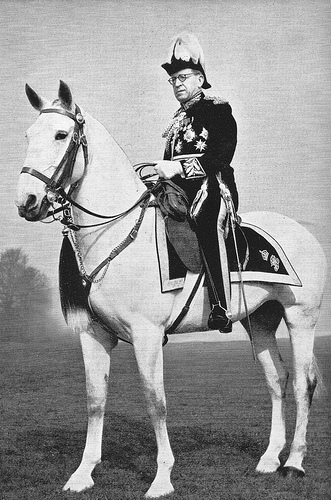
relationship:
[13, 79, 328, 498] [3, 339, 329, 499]
horse on grass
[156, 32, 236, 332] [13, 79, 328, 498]
man on horse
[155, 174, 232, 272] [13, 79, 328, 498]
saddle on horse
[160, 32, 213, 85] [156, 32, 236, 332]
cap on man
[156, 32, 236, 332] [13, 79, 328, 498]
man and horse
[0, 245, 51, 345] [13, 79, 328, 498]
tree behind horse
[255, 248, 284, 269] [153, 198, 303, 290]
emblem on blanket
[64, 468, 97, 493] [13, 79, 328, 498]
hoof on horse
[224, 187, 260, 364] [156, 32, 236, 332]
saber on man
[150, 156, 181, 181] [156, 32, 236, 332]
hand on man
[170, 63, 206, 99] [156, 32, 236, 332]
head of man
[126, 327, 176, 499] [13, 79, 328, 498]
leg of horse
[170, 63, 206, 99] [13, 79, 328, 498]
head on horse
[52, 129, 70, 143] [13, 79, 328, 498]
eye of horse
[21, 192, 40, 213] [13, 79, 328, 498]
nose of horse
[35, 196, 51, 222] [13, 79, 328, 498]
mouth of horse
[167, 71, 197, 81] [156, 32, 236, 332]
glasses on man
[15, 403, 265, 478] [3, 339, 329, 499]
shadow on grass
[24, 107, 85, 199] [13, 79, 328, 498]
bridal on horse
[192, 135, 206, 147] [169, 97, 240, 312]
star on uniform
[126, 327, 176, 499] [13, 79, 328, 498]
leg on horse